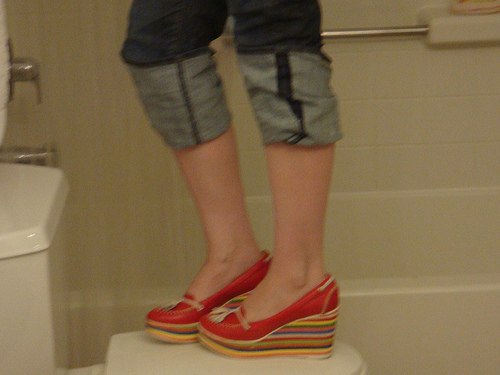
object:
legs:
[196, 0, 339, 361]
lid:
[103, 328, 368, 375]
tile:
[114, 185, 185, 288]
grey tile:
[375, 94, 500, 149]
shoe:
[143, 250, 273, 345]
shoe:
[197, 273, 337, 360]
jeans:
[118, 1, 343, 151]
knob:
[8, 57, 39, 83]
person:
[119, 1, 342, 358]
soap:
[449, 0, 499, 16]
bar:
[223, 25, 428, 43]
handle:
[5, 58, 44, 106]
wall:
[0, 6, 500, 375]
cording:
[207, 304, 251, 331]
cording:
[156, 296, 204, 313]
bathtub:
[63, 186, 497, 375]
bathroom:
[0, 1, 498, 373]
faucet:
[0, 140, 58, 168]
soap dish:
[416, 4, 500, 46]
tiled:
[331, 141, 380, 194]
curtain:
[29, 0, 218, 366]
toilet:
[0, 161, 369, 375]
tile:
[372, 99, 476, 149]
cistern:
[2, 160, 75, 375]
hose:
[64, 365, 100, 375]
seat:
[105, 320, 365, 375]